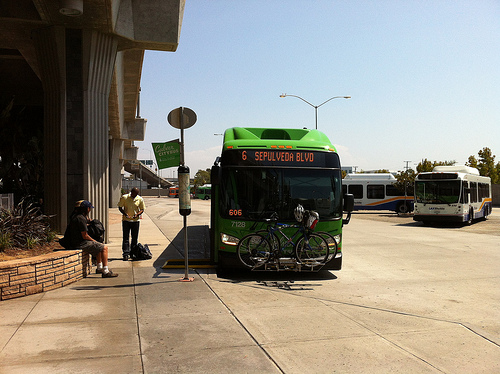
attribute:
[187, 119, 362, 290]
bus — green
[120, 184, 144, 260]
black man — black , standing